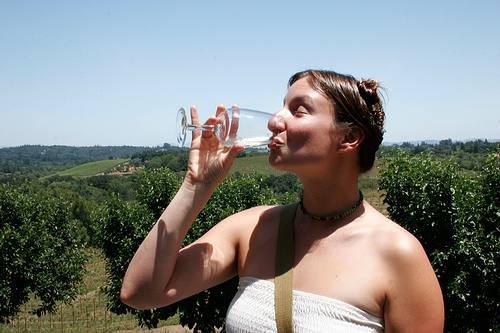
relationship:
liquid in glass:
[222, 136, 274, 148] [176, 109, 277, 153]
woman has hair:
[121, 69, 445, 333] [287, 68, 385, 174]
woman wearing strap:
[121, 69, 445, 333] [274, 204, 295, 332]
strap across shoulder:
[274, 204, 295, 332] [243, 200, 301, 241]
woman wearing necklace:
[121, 69, 445, 333] [299, 189, 362, 222]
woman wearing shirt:
[121, 69, 445, 333] [226, 275, 387, 333]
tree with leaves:
[3, 166, 499, 332] [4, 153, 499, 332]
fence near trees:
[2, 300, 114, 331] [3, 166, 499, 332]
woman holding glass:
[121, 69, 445, 333] [176, 109, 277, 153]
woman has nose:
[121, 69, 445, 333] [269, 108, 286, 133]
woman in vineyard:
[121, 69, 445, 333] [1, 145, 499, 332]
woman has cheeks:
[121, 69, 445, 333] [288, 119, 324, 154]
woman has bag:
[121, 69, 445, 333] [274, 204, 295, 332]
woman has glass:
[121, 69, 445, 333] [176, 109, 277, 153]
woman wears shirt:
[121, 69, 445, 333] [226, 275, 387, 333]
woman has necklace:
[121, 69, 445, 333] [299, 189, 362, 222]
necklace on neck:
[299, 189, 362, 222] [303, 176, 360, 217]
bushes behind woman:
[2, 153, 500, 332] [121, 69, 445, 333]